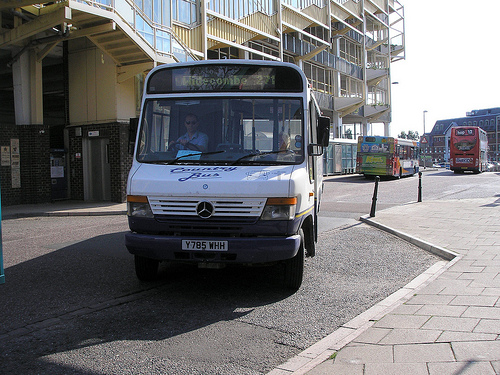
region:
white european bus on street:
[111, 44, 318, 279]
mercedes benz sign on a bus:
[183, 197, 220, 222]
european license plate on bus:
[176, 236, 230, 256]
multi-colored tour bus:
[350, 129, 436, 180]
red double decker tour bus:
[448, 116, 490, 181]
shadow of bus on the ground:
[11, 236, 127, 348]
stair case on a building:
[297, 4, 409, 76]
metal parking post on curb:
[364, 169, 386, 219]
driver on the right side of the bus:
[141, 101, 216, 183]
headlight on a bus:
[119, 188, 156, 222]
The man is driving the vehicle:
[92, 55, 266, 237]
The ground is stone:
[356, 274, 441, 369]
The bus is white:
[92, 165, 329, 279]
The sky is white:
[395, 17, 476, 146]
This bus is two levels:
[450, 105, 497, 225]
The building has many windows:
[252, 13, 404, 185]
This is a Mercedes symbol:
[187, 195, 228, 229]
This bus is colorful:
[359, 123, 419, 185]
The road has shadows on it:
[11, 211, 180, 373]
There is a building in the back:
[418, 92, 498, 178]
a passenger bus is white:
[122, 54, 325, 296]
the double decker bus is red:
[448, 122, 490, 172]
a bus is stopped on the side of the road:
[357, 132, 422, 181]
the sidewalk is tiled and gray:
[282, 195, 499, 371]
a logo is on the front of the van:
[191, 195, 217, 220]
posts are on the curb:
[361, 170, 431, 221]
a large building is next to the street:
[18, 2, 410, 211]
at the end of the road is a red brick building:
[419, 107, 497, 170]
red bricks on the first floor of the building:
[15, 120, 132, 222]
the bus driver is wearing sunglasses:
[162, 110, 214, 166]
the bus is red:
[412, 96, 494, 213]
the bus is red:
[399, 87, 499, 165]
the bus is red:
[430, 129, 486, 174]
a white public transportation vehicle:
[117, 48, 344, 298]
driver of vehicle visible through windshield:
[148, 92, 235, 164]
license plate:
[171, 233, 232, 260]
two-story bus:
[446, 120, 490, 185]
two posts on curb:
[360, 163, 445, 237]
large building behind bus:
[410, 98, 498, 172]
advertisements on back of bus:
[348, 133, 403, 185]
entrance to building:
[64, 101, 121, 213]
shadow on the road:
[1, 220, 288, 369]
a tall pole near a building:
[410, 100, 472, 175]